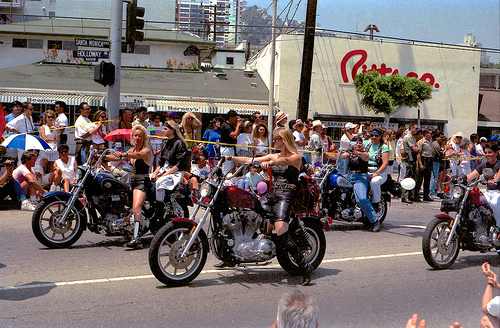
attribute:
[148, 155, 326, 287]
motorcycle — red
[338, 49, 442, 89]
sign — large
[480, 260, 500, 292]
hands — clapping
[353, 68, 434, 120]
tree — green, leafy, small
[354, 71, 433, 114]
leaves — green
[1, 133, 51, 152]
umbrella — blue, white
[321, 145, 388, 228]
motorcycle — blue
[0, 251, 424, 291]
line — white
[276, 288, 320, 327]
head — balding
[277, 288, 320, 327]
hair — gray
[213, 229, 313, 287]
boots — black, tall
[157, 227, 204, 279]
wheel — silver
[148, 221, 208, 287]
tire — black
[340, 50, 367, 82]
letter — red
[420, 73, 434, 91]
letter — red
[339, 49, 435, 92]
letters — red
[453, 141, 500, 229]
person — smiling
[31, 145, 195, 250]
harley — blue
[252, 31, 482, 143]
building — white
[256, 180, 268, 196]
balloon — held, white